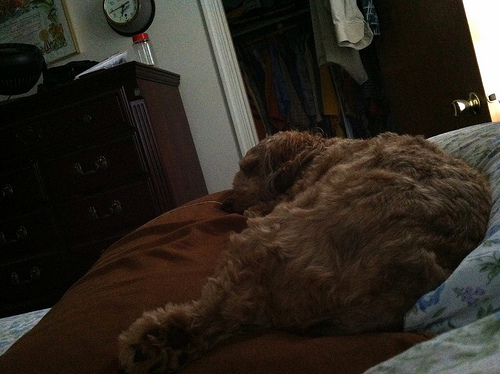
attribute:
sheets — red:
[104, 241, 185, 289]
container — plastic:
[129, 28, 159, 70]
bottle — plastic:
[123, 32, 168, 67]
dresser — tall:
[3, 57, 218, 297]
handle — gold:
[68, 153, 108, 177]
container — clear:
[129, 31, 154, 63]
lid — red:
[129, 32, 147, 42]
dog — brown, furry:
[119, 127, 490, 372]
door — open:
[321, 0, 498, 145]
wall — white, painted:
[0, 4, 257, 193]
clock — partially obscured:
[92, 1, 164, 43]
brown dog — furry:
[110, 126, 491, 372]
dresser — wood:
[0, 60, 212, 315]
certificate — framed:
[11, 7, 73, 56]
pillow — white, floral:
[398, 110, 496, 353]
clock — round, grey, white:
[96, 0, 156, 39]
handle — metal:
[451, 94, 483, 119]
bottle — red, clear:
[128, 27, 178, 85]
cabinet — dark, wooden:
[0, 59, 207, 316]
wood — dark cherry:
[151, 99, 186, 185]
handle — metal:
[69, 150, 115, 177]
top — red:
[129, 27, 149, 43]